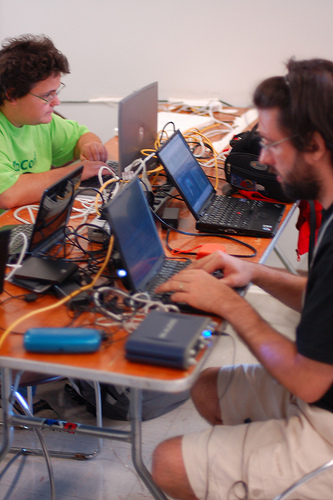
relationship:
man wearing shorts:
[142, 58, 329, 500] [187, 357, 329, 499]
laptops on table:
[6, 79, 283, 316] [1, 81, 305, 396]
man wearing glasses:
[142, 58, 329, 500] [256, 131, 307, 162]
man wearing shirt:
[1, 29, 108, 212] [1, 114, 91, 195]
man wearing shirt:
[142, 58, 329, 500] [290, 216, 332, 413]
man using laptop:
[142, 58, 329, 500] [107, 175, 240, 310]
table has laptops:
[1, 81, 305, 396] [6, 79, 283, 316]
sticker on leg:
[40, 417, 83, 435] [1, 367, 179, 498]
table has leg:
[1, 81, 305, 396] [1, 367, 179, 498]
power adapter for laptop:
[155, 196, 181, 234] [148, 125, 291, 241]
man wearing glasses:
[1, 29, 108, 212] [30, 79, 68, 110]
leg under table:
[1, 367, 179, 498] [1, 81, 305, 396]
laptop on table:
[148, 125, 291, 241] [1, 81, 305, 396]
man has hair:
[1, 29, 108, 212] [1, 36, 65, 97]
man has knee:
[142, 58, 329, 500] [190, 363, 220, 420]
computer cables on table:
[21, 141, 233, 333] [1, 81, 305, 396]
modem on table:
[221, 134, 299, 198] [1, 81, 305, 396]